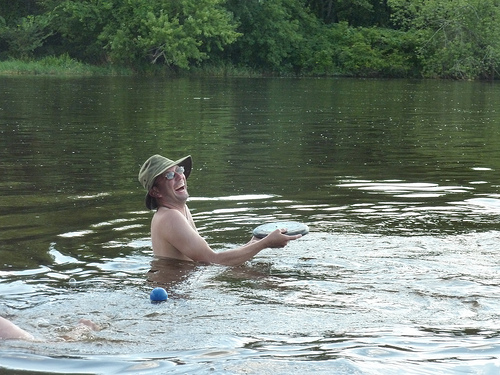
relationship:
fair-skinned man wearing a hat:
[139, 153, 304, 269] [134, 149, 197, 211]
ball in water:
[147, 285, 167, 301] [5, 77, 500, 371]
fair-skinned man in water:
[139, 153, 304, 269] [5, 77, 500, 371]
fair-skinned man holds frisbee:
[139, 153, 304, 269] [251, 220, 309, 241]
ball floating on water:
[149, 288, 168, 301] [126, 97, 496, 327]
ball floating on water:
[149, 288, 168, 301] [293, 130, 421, 314]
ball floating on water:
[149, 288, 168, 301] [324, 216, 414, 324]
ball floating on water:
[149, 288, 168, 301] [5, 77, 500, 371]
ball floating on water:
[149, 288, 168, 301] [1, 272, 498, 373]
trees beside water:
[21, 17, 72, 62] [264, 94, 495, 181]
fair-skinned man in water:
[139, 153, 304, 269] [42, 24, 499, 339]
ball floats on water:
[149, 288, 168, 301] [27, 87, 485, 352]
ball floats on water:
[149, 288, 168, 301] [222, 103, 442, 253]